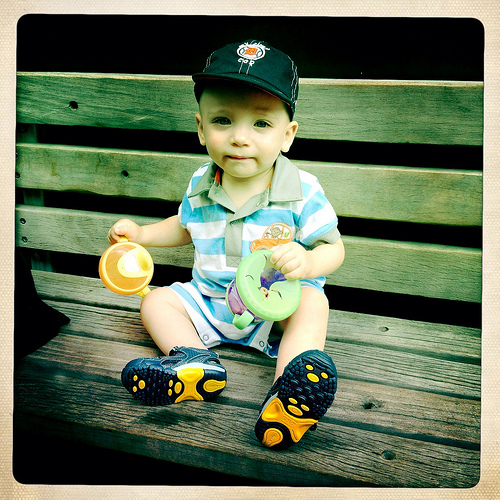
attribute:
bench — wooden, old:
[17, 64, 464, 486]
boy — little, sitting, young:
[105, 41, 340, 447]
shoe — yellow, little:
[254, 347, 337, 451]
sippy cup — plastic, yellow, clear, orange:
[97, 236, 154, 297]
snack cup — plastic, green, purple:
[224, 250, 302, 330]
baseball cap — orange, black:
[192, 39, 299, 121]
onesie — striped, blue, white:
[167, 150, 340, 359]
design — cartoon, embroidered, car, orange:
[249, 220, 294, 254]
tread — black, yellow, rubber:
[255, 356, 338, 450]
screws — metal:
[18, 216, 26, 226]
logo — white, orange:
[235, 42, 271, 67]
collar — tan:
[187, 153, 303, 204]